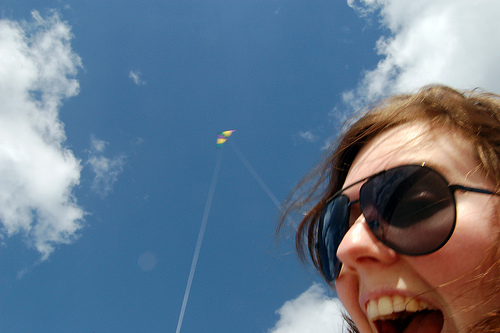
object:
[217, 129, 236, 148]
kite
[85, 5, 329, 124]
sky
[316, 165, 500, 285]
glasses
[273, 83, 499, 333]
woman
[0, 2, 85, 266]
cloud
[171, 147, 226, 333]
string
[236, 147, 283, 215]
string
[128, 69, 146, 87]
cloud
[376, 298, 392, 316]
teeth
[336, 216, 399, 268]
nose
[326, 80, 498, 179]
har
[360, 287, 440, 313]
lips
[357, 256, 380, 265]
nostril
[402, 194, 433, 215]
eye